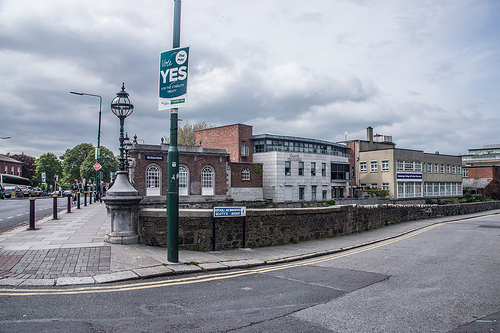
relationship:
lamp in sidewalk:
[69, 87, 105, 156] [3, 187, 118, 289]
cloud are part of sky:
[0, 0, 497, 162] [217, 8, 489, 145]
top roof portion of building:
[255, 132, 355, 154] [253, 132, 352, 210]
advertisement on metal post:
[157, 46, 192, 109] [158, 121, 186, 268]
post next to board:
[136, 34, 208, 279] [210, 201, 248, 217]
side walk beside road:
[18, 192, 107, 278] [0, 194, 91, 230]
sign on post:
[157, 47, 189, 112] [166, 0, 179, 263]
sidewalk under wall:
[32, 227, 58, 274] [114, 203, 496, 256]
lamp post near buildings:
[84, 90, 106, 190] [133, 112, 496, 204]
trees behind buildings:
[31, 140, 116, 189] [116, 118, 498, 235]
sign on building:
[393, 172, 425, 182] [337, 125, 462, 198]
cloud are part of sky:
[0, 0, 497, 162] [249, 15, 374, 107]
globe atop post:
[111, 92, 134, 119] [110, 84, 130, 171]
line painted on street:
[311, 250, 338, 270] [4, 210, 497, 331]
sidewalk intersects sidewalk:
[0, 208, 500, 289] [2, 198, 116, 288]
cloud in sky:
[0, 0, 497, 162] [4, 6, 498, 155]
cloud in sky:
[0, 0, 497, 162] [0, 2, 498, 183]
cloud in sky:
[224, 1, 498, 151] [0, 2, 498, 183]